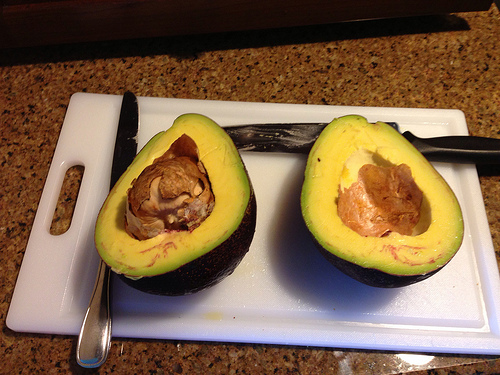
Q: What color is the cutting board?
A: White.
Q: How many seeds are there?
A: One.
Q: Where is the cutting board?
A: On the counter.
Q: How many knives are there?
A: Two.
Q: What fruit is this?
A: Avocado.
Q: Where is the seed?
A: The left half.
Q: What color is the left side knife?
A: Silver.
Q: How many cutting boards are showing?
A: One.